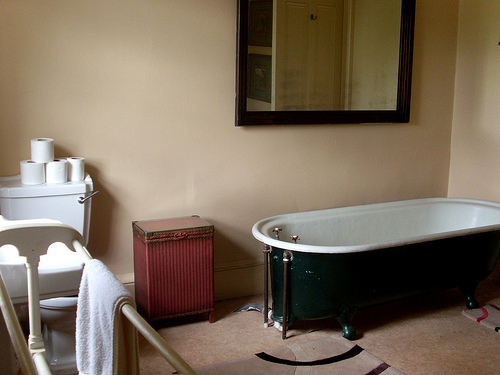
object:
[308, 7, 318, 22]
hook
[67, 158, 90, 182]
roll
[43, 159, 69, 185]
roll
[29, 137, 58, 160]
roll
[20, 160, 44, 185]
roll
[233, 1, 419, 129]
mirror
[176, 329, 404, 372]
rug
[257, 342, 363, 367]
circular lines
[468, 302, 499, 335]
circular lines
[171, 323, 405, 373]
towel mat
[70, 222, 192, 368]
rod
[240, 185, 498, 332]
tub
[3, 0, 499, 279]
walls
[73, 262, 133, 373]
towel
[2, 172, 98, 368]
toilet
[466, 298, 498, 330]
towel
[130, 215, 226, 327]
hamper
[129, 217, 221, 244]
lid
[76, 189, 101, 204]
handle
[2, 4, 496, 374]
bathroom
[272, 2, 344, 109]
door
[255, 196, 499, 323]
bathtub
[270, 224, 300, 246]
faucets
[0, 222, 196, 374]
rack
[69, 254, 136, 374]
clothes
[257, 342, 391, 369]
stripes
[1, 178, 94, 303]
tank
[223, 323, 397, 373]
mat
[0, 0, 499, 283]
wall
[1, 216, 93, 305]
sink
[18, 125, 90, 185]
paper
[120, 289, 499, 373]
floor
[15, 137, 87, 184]
rolls